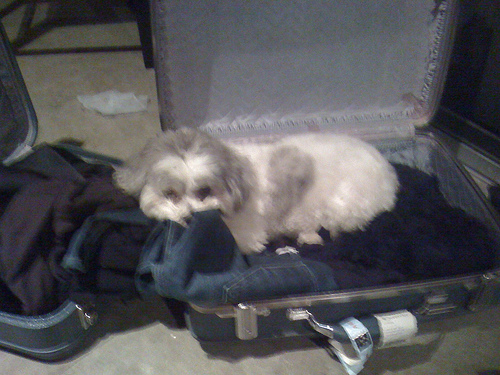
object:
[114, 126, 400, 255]
dog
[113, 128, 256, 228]
head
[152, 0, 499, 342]
suitcase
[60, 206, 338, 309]
blue jeans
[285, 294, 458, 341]
handle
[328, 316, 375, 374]
tag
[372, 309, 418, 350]
tag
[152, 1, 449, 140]
top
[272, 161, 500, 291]
clothing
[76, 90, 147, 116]
tissue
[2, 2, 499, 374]
floor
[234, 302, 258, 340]
lock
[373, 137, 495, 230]
lining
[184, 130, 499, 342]
bottom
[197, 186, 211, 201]
left eye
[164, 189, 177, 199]
right eye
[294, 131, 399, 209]
backside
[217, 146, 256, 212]
right ear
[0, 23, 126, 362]
suitcase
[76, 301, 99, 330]
clasp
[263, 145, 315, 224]
spot